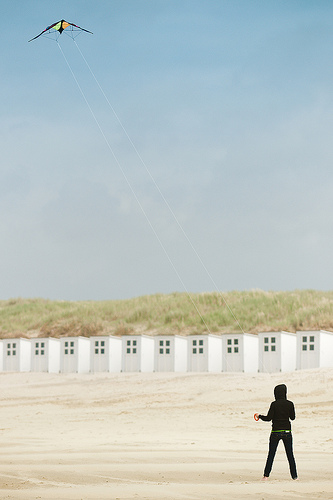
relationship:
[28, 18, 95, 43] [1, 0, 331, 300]
kite flying in sky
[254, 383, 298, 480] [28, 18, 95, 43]
woman flying kite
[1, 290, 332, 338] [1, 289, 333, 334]
grass growing on hill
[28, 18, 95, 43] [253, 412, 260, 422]
kite has handle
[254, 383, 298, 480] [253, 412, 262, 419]
woman has hand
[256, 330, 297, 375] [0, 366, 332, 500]
building sitting on beach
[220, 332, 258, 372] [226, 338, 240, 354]
building has window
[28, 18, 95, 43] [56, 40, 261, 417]
kite has string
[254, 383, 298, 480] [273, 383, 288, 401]
woman has head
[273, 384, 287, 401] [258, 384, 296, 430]
hood on top of jacket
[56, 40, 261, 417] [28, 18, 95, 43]
string attached to kite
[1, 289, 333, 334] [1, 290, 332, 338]
hill had grass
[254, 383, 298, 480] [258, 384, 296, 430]
woman wearing jacket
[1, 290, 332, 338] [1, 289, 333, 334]
grass on top of hill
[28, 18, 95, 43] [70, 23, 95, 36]
kite has wing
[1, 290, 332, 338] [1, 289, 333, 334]
grass spread over hill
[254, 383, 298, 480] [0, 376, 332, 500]
woman standing on beach